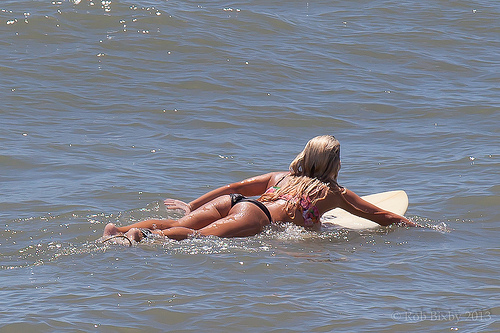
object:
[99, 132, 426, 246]
woman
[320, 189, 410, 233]
surfboard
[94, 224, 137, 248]
rope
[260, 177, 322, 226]
shirt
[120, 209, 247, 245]
legs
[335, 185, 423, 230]
right arm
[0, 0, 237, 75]
reflection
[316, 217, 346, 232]
shadow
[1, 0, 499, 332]
water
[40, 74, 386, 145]
small waves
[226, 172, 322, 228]
bikini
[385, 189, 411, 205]
tip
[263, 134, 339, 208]
hair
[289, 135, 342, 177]
head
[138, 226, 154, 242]
ankle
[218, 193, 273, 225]
bottom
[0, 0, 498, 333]
waves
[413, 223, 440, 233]
hand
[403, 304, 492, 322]
watermark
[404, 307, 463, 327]
rob bixby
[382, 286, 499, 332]
corner